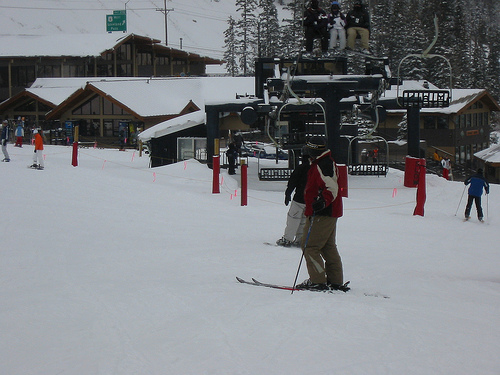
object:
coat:
[464, 173, 489, 197]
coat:
[303, 149, 343, 218]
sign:
[105, 14, 127, 35]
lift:
[258, 100, 329, 182]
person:
[276, 153, 311, 248]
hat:
[304, 132, 328, 150]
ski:
[260, 238, 303, 248]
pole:
[289, 218, 312, 296]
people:
[345, 1, 372, 51]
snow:
[147, 86, 181, 105]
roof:
[81, 77, 253, 116]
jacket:
[464, 171, 490, 197]